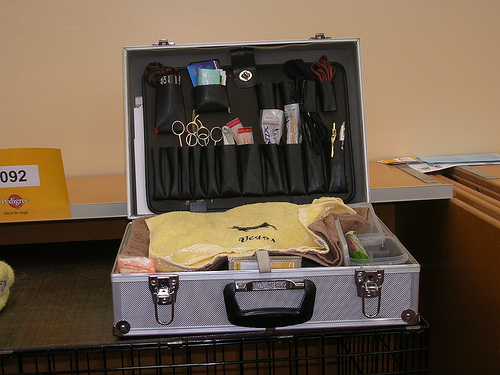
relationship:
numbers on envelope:
[1, 170, 27, 183] [2, 147, 70, 221]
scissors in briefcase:
[191, 110, 196, 134] [108, 32, 422, 334]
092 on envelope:
[2, 169, 26, 183] [2, 147, 70, 221]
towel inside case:
[143, 197, 354, 277] [109, 41, 423, 354]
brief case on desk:
[107, 33, 421, 340] [22, 221, 126, 345]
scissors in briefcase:
[168, 114, 223, 144] [111, 30, 484, 349]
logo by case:
[227, 221, 277, 242] [109, 41, 423, 354]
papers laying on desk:
[376, 150, 497, 175] [60, 161, 454, 220]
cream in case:
[260, 110, 282, 147] [109, 41, 423, 354]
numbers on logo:
[1, 167, 31, 184] [227, 221, 277, 242]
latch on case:
[137, 276, 188, 326] [109, 41, 423, 354]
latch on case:
[353, 265, 390, 300] [109, 41, 423, 354]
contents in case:
[165, 196, 316, 266] [101, 75, 483, 358]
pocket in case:
[150, 140, 350, 201] [129, 58, 361, 209]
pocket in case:
[261, 136, 291, 200] [129, 58, 361, 209]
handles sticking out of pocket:
[173, 122, 223, 144] [149, 145, 347, 192]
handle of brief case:
[223, 279, 317, 329] [107, 33, 421, 340]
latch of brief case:
[354, 268, 385, 318] [107, 33, 421, 340]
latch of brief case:
[147, 274, 180, 326] [107, 33, 421, 340]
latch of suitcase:
[151, 38, 175, 46] [99, 34, 431, 346]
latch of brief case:
[308, 32, 329, 35] [107, 33, 421, 340]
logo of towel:
[227, 221, 277, 242] [150, 203, 361, 266]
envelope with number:
[0, 147, 72, 223] [1, 159, 38, 181]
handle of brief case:
[223, 274, 320, 329] [107, 33, 422, 351]